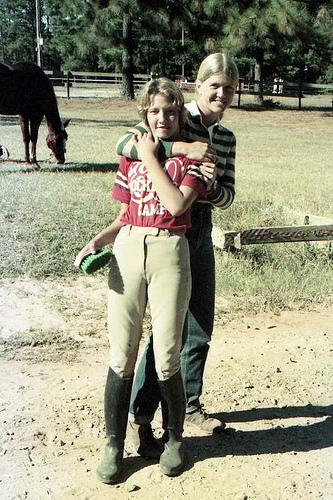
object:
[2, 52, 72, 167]
horse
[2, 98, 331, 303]
grass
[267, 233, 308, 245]
wall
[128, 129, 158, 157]
hand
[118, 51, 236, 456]
girl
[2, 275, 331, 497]
dirt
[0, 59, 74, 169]
horse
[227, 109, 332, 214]
field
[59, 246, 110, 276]
brush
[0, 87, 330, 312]
grass